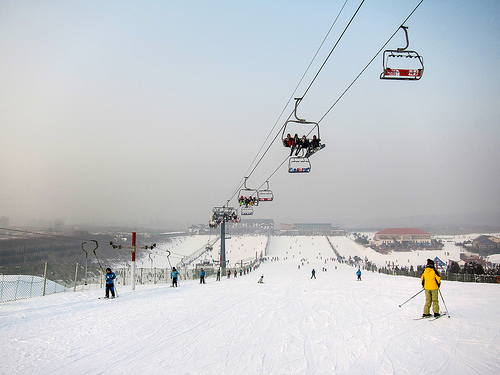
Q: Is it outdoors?
A: Yes, it is outdoors.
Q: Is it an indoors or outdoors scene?
A: It is outdoors.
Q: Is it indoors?
A: No, it is outdoors.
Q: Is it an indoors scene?
A: No, it is outdoors.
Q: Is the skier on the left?
A: Yes, the skier is on the left of the image.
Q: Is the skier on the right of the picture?
A: No, the skier is on the left of the image.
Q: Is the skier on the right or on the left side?
A: The skier is on the left of the image.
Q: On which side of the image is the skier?
A: The skier is on the left of the image.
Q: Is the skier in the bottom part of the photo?
A: Yes, the skier is in the bottom of the image.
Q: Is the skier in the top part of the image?
A: No, the skier is in the bottom of the image.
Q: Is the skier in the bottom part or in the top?
A: The skier is in the bottom of the image.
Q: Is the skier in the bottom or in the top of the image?
A: The skier is in the bottom of the image.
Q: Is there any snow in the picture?
A: Yes, there is snow.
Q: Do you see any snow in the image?
A: Yes, there is snow.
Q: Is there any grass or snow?
A: Yes, there is snow.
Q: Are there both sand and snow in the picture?
A: No, there is snow but no sand.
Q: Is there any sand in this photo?
A: No, there is no sand.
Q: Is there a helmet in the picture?
A: No, there are no helmets.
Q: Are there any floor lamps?
A: No, there are no floor lamps.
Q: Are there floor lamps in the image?
A: No, there are no floor lamps.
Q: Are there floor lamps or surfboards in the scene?
A: No, there are no floor lamps or surfboards.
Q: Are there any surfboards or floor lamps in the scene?
A: No, there are no floor lamps or surfboards.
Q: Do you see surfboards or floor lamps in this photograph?
A: No, there are no floor lamps or surfboards.